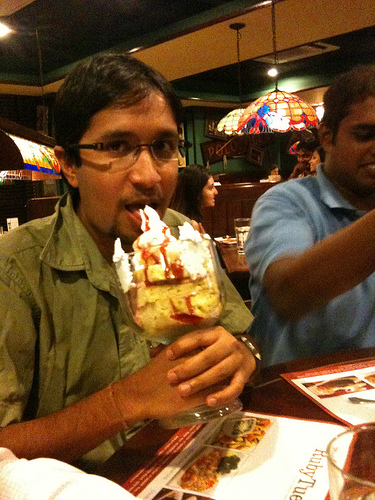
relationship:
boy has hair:
[3, 49, 264, 460] [49, 48, 188, 213]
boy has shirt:
[3, 49, 264, 460] [0, 193, 251, 472]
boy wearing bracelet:
[3, 49, 264, 460] [105, 381, 135, 428]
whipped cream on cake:
[110, 201, 210, 295] [75, 218, 280, 304]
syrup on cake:
[139, 240, 184, 284] [86, 199, 245, 336]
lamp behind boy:
[214, 2, 321, 145] [285, 139, 313, 179]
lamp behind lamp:
[237, 2, 321, 135] [214, 2, 321, 145]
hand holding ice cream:
[166, 323, 256, 408] [112, 204, 225, 341]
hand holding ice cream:
[144, 336, 231, 417] [112, 204, 225, 341]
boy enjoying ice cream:
[3, 46, 264, 459] [105, 205, 245, 429]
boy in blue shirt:
[241, 62, 375, 366] [243, 162, 374, 364]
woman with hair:
[176, 162, 222, 232] [167, 160, 213, 222]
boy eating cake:
[3, 46, 264, 459] [112, 204, 229, 346]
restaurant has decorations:
[3, 1, 374, 498] [174, 113, 270, 177]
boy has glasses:
[3, 46, 264, 459] [55, 135, 189, 162]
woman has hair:
[168, 162, 218, 235] [167, 160, 213, 222]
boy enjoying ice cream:
[3, 46, 264, 459] [110, 202, 227, 345]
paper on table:
[119, 408, 353, 499] [3, 345, 373, 499]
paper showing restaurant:
[119, 408, 353, 499] [3, 1, 374, 498]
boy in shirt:
[241, 62, 375, 366] [245, 167, 373, 359]